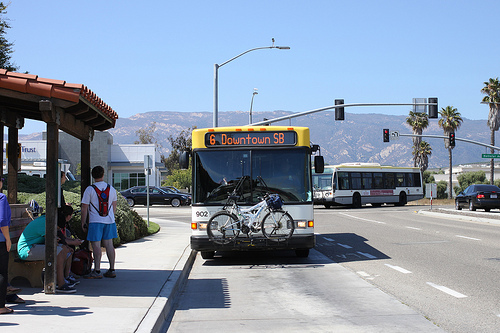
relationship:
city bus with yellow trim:
[187, 118, 322, 255] [198, 126, 301, 132]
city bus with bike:
[187, 118, 322, 255] [205, 189, 297, 249]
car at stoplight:
[448, 174, 500, 218] [435, 129, 457, 152]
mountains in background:
[334, 130, 375, 150] [363, 87, 390, 97]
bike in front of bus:
[205, 189, 297, 249] [321, 155, 428, 207]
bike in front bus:
[205, 189, 297, 249] [321, 155, 428, 207]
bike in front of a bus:
[205, 189, 297, 249] [321, 155, 428, 207]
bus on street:
[321, 155, 428, 207] [247, 283, 313, 315]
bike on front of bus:
[205, 193, 295, 247] [321, 155, 428, 207]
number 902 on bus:
[195, 209, 210, 219] [321, 155, 428, 207]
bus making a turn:
[321, 155, 428, 207] [322, 177, 343, 204]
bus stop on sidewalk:
[0, 70, 118, 295] [132, 249, 161, 277]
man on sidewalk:
[73, 165, 134, 280] [132, 249, 161, 277]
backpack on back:
[90, 183, 114, 217] [96, 192, 99, 221]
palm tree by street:
[435, 102, 468, 203] [247, 283, 313, 315]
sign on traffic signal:
[414, 95, 440, 115] [382, 125, 392, 146]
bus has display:
[321, 155, 428, 207] [206, 129, 290, 147]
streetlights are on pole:
[332, 99, 350, 121] [442, 154, 457, 200]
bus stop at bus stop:
[46, 105, 94, 172] [0, 70, 118, 295]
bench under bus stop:
[13, 262, 45, 279] [0, 70, 118, 295]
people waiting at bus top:
[1, 163, 138, 297] [48, 96, 106, 139]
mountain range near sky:
[156, 107, 191, 121] [333, 41, 417, 82]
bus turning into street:
[321, 155, 428, 207] [247, 283, 313, 315]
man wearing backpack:
[81, 165, 117, 278] [98, 193, 105, 208]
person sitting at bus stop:
[19, 209, 65, 283] [46, 105, 94, 172]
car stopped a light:
[448, 174, 500, 218] [383, 129, 390, 135]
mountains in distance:
[334, 130, 375, 150] [299, 83, 315, 97]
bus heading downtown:
[321, 155, 428, 207] [27, 12, 488, 319]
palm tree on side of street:
[435, 102, 468, 203] [161, 247, 444, 333]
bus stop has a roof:
[46, 105, 94, 172] [15, 72, 57, 93]